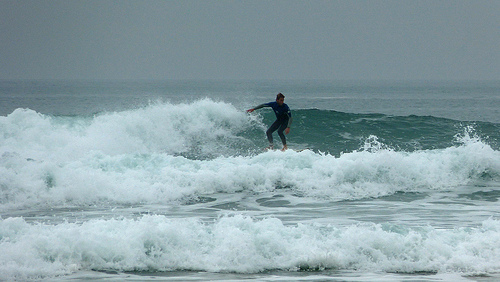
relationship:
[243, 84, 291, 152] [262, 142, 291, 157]
man balancing on surfboard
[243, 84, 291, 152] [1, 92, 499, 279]
man looking toward waves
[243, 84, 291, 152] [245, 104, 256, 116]
man has right hand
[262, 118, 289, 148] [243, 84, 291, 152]
legs on man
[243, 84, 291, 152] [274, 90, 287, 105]
man has a head